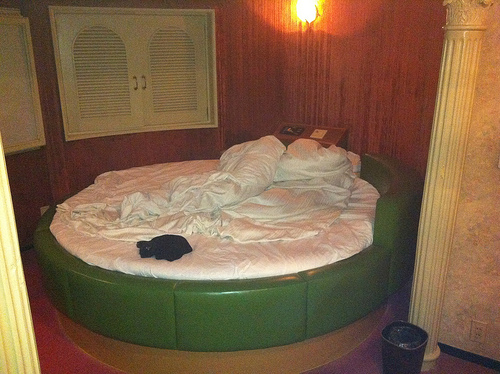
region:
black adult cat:
[135, 234, 192, 262]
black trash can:
[378, 318, 430, 373]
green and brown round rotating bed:
[35, 117, 422, 372]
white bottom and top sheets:
[49, 130, 382, 277]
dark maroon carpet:
[20, 250, 498, 372]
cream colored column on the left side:
[1, 130, 41, 371]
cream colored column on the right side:
[402, 0, 493, 371]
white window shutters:
[47, 5, 220, 142]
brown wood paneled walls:
[2, 0, 449, 255]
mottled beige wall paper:
[436, 0, 499, 364]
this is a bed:
[25, 125, 460, 340]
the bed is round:
[17, 136, 429, 346]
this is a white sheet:
[53, 137, 385, 277]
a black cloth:
[121, 228, 192, 278]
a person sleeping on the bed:
[180, 113, 279, 218]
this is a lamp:
[291, 3, 339, 45]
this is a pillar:
[408, 0, 498, 368]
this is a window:
[68, 25, 133, 116]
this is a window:
[142, 22, 212, 122]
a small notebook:
[310, 109, 327, 151]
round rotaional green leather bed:
[36, 136, 417, 353]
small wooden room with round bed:
[5, 5, 436, 368]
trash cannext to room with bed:
[375, 320, 430, 370]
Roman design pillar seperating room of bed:
[403, 5, 496, 366]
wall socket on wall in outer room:
[470, 320, 487, 343]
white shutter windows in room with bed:
[45, 5, 224, 144]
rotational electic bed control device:
[270, 121, 346, 147]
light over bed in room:
[284, 1, 325, 26]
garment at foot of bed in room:
[135, 235, 192, 261]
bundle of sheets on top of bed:
[125, 136, 359, 240]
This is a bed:
[31, 111, 422, 372]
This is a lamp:
[280, 0, 341, 37]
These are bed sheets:
[46, 130, 401, 283]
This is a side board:
[48, 3, 239, 144]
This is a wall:
[6, 11, 436, 180]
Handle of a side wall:
[139, 65, 151, 97]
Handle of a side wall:
[132, 73, 142, 92]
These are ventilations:
[69, 18, 135, 131]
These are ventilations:
[146, 15, 206, 122]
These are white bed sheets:
[39, 133, 404, 274]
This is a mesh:
[67, 15, 142, 123]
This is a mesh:
[149, 11, 209, 122]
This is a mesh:
[235, 120, 365, 270]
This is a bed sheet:
[170, 142, 370, 303]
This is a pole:
[380, 306, 435, 366]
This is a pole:
[395, 25, 461, 351]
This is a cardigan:
[120, 225, 207, 275]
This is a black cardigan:
[131, 220, 203, 278]